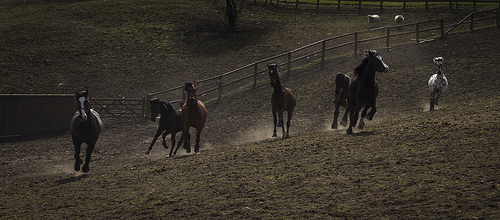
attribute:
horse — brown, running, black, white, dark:
[68, 88, 100, 177]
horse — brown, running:
[175, 79, 212, 151]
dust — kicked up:
[55, 159, 86, 176]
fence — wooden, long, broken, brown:
[0, 6, 499, 131]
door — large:
[92, 95, 146, 119]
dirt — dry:
[30, 163, 65, 178]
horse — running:
[267, 64, 295, 138]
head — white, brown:
[186, 82, 196, 110]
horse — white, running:
[426, 58, 449, 111]